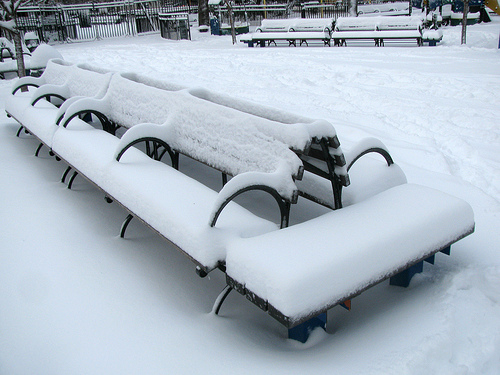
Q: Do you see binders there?
A: No, there are no binders.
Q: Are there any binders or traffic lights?
A: No, there are no binders or traffic lights.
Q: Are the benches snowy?
A: Yes, the benches are snowy.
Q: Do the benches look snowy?
A: Yes, the benches are snowy.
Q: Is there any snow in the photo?
A: Yes, there is snow.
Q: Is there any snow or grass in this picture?
A: Yes, there is snow.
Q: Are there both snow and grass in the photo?
A: No, there is snow but no grass.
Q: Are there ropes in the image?
A: No, there are no ropes.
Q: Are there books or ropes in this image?
A: No, there are no ropes or books.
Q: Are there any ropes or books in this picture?
A: No, there are no ropes or books.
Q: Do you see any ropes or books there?
A: No, there are no ropes or books.